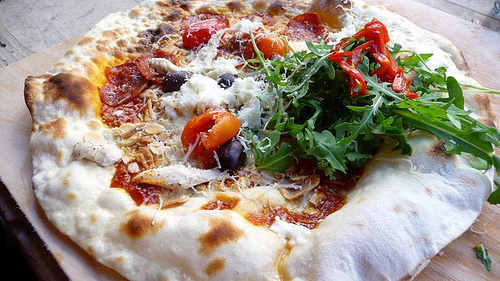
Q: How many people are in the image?
A: 0.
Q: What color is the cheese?
A: White.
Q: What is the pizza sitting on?
A: A table.